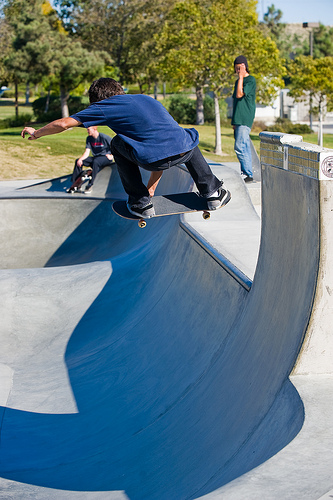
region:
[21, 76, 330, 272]
kids at skateboard park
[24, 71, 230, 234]
guy balanced on ledge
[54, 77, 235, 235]
guy with two feet on skateboard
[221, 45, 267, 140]
person wearing green shirt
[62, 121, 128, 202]
person sitting down with skateboard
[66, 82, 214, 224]
guy has one hand on skateboard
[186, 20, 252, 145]
green leaves on tree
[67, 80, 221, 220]
blue jeans and shirt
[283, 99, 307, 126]
trash container near walkway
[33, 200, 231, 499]
cement walls of skateboard park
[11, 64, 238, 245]
a skater balancing on the edge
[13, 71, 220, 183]
skater wears a blue shirt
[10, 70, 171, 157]
a skater has left hand extended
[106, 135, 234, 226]
right hand of skater is holding the skateboard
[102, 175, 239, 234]
skateboard is color black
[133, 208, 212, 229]
wheels of skateboard are yellow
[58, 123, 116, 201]
boy sits on side of skateboard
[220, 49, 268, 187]
boy holding a skateboard with right hand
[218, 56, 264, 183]
boy wears a green tee shirt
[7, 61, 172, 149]
skater has black hair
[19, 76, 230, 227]
boy is skateboarding down ramp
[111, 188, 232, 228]
boy on black skateboard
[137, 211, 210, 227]
skateboard has yellow wheels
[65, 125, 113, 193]
boy sitting on cement skate rink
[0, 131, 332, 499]
skate rink is curved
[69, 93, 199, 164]
boy wearing blue shirt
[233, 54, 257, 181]
standing boy is covering his face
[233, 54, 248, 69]
boy wearing black hat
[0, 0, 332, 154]
green trees behind boys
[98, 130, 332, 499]
tall ramp in skate rink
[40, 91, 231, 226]
boy with blue shirt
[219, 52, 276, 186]
boy with green shirt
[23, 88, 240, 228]
boy riding on skateboard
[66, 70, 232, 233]
boy with short hair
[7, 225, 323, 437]
skateboard ramp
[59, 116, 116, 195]
boy sitting down on ramp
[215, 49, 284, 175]
boy with hand over his eye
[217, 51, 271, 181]
boy with beanie on his head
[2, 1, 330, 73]
green forest trees in ground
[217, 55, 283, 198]
boy with light blue jeans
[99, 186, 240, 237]
skateboard on top of skate ramp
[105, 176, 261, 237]
skateboard is black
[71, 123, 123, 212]
man sitting on skateboard ramp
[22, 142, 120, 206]
man has one foot on the skateboard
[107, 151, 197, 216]
skateboarder is holding on the the skateboard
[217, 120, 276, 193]
man holding a skateboard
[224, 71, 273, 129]
man is wearing a green shirt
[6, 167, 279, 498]
shadow on the skating ramp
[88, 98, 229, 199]
skater's shirt is blue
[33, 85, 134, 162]
skater has is arm up